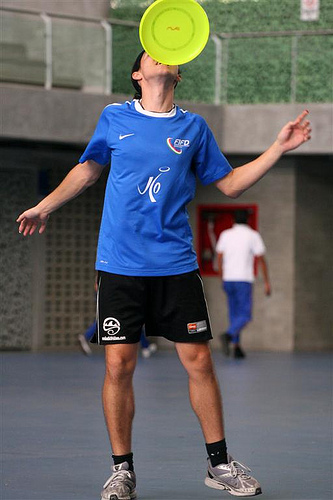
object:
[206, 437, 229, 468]
black sock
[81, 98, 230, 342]
uniform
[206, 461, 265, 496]
sneaker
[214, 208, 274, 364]
man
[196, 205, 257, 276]
fire hose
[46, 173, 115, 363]
stands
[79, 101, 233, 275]
blue shirt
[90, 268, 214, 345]
black shorts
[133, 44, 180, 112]
mans head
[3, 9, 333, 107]
fence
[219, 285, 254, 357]
one foot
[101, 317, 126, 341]
white logo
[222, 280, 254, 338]
blue pants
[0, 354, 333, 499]
grey floor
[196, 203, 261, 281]
case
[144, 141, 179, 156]
chin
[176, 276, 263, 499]
leg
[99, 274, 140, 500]
leg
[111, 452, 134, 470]
sock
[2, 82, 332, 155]
wall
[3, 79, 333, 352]
distance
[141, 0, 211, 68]
frisbee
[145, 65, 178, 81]
chin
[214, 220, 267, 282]
shirt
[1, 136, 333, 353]
wall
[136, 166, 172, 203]
design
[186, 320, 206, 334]
tag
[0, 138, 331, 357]
background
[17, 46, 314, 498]
boy